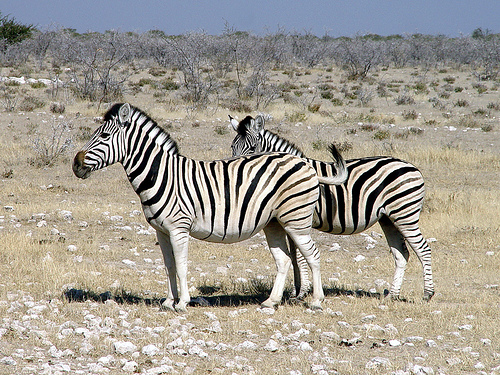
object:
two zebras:
[71, 103, 436, 313]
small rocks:
[457, 323, 475, 333]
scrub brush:
[308, 102, 325, 113]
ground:
[0, 34, 500, 375]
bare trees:
[340, 39, 363, 77]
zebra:
[65, 101, 348, 315]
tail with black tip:
[316, 142, 349, 187]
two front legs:
[154, 230, 191, 314]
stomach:
[190, 199, 276, 244]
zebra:
[226, 113, 435, 302]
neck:
[122, 122, 176, 200]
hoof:
[377, 295, 398, 306]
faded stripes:
[176, 240, 188, 246]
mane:
[103, 102, 180, 158]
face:
[72, 121, 124, 180]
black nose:
[71, 152, 84, 172]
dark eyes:
[98, 132, 112, 139]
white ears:
[118, 102, 131, 125]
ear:
[228, 114, 240, 131]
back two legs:
[259, 218, 294, 311]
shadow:
[62, 286, 289, 307]